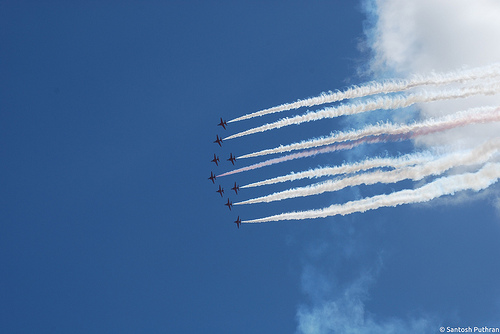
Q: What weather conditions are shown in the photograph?
A: It is clear.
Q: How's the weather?
A: It is clear.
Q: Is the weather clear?
A: Yes, it is clear.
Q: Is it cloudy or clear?
A: It is clear.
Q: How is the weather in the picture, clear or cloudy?
A: It is clear.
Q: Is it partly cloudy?
A: No, it is clear.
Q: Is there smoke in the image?
A: Yes, there is smoke.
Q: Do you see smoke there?
A: Yes, there is smoke.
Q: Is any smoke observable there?
A: Yes, there is smoke.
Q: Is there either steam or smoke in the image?
A: Yes, there is smoke.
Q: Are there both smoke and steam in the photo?
A: No, there is smoke but no steam.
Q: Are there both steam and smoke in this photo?
A: No, there is smoke but no steam.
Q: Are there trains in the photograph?
A: No, there are no trains.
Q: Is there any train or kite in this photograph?
A: No, there are no trains or kites.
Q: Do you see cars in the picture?
A: No, there are no cars.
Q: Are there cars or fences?
A: No, there are no cars or fences.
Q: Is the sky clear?
A: Yes, the sky is clear.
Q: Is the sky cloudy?
A: No, the sky is clear.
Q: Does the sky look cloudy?
A: No, the sky is clear.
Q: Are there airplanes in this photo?
A: Yes, there is an airplane.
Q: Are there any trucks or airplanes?
A: Yes, there is an airplane.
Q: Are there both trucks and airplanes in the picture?
A: No, there is an airplane but no trucks.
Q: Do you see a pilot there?
A: No, there are no pilots.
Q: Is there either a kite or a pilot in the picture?
A: No, there are no pilots or kites.